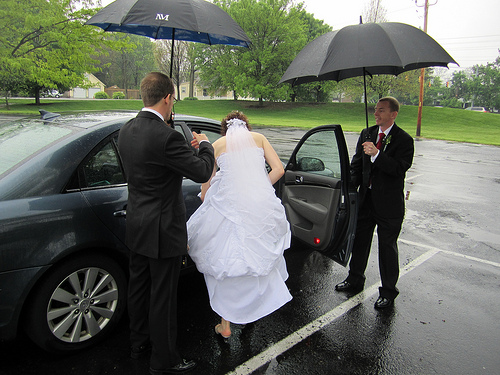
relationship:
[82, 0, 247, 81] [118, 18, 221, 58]
umbrella with sky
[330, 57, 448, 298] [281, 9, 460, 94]
man holding umbrella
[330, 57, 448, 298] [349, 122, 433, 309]
man wearing suit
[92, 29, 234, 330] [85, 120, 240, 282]
man wearing suit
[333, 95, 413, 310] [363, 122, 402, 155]
man wearing shirt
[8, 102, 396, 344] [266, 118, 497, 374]
car parked in parking lot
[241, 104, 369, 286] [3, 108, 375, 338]
door on car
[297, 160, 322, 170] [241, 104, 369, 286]
mirror on door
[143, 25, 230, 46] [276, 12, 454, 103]
clouds underneath umbrella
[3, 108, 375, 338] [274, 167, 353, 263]
car with open door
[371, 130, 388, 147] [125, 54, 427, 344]
red tie on groomsmen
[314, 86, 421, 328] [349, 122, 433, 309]
man wearing suit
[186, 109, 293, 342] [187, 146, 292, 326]
woman in white dress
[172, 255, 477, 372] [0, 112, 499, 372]
white line in parking lot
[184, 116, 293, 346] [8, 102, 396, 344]
bride getting into car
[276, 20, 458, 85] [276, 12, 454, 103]
top of umbrella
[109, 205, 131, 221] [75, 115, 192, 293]
handle on passenger door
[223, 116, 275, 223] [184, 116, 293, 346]
veil on bride